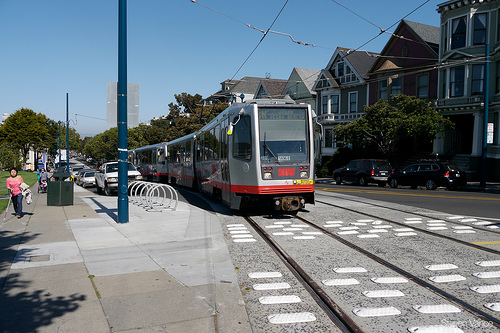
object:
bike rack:
[127, 181, 179, 212]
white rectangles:
[226, 215, 500, 333]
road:
[223, 196, 484, 330]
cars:
[77, 171, 101, 189]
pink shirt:
[6, 175, 23, 197]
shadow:
[86, 197, 117, 222]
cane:
[3, 196, 11, 221]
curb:
[58, 161, 119, 195]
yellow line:
[310, 187, 500, 201]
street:
[315, 194, 500, 254]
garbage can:
[47, 168, 74, 206]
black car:
[387, 163, 468, 190]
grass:
[0, 171, 38, 212]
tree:
[333, 93, 455, 158]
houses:
[308, 0, 498, 163]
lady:
[6, 168, 24, 219]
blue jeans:
[11, 193, 23, 215]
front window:
[259, 107, 309, 164]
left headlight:
[263, 172, 272, 180]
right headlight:
[299, 171, 308, 178]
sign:
[107, 80, 139, 122]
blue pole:
[118, 3, 129, 223]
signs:
[25, 162, 34, 171]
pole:
[471, 112, 485, 155]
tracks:
[245, 213, 499, 333]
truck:
[95, 161, 145, 195]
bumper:
[232, 184, 315, 212]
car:
[127, 98, 316, 216]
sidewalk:
[40, 200, 220, 324]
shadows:
[0, 230, 85, 333]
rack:
[128, 181, 179, 211]